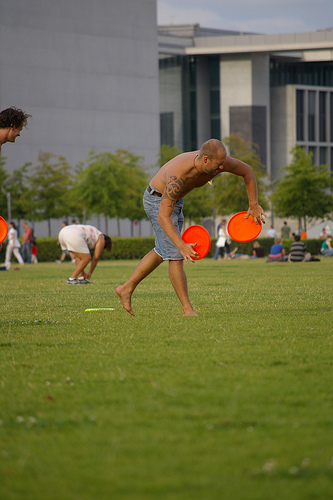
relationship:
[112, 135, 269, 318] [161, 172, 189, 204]
man has tattoo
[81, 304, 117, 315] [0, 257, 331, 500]
frisbee lying on grass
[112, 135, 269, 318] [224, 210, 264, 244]
man trying to throw frisbee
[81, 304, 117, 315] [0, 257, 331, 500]
frisbee lying in grass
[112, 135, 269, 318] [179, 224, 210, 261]
man holding frisbee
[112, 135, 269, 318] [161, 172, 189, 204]
man has a tattoo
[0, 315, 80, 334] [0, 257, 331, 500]
patch of grass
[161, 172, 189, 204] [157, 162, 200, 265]
tattoo printed on arm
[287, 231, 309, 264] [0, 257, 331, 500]
person sitting in grass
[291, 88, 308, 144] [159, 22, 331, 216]
window in side of building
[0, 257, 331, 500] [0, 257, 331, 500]
grass covering grass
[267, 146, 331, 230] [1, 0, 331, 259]
tree standing in background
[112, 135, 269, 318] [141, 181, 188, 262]
man wearing shorts